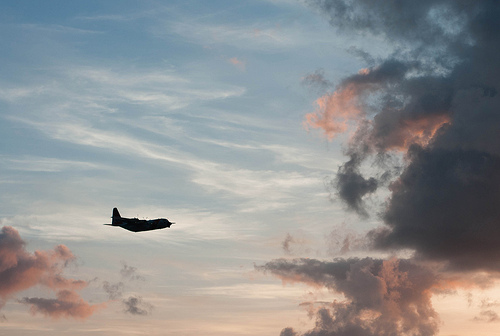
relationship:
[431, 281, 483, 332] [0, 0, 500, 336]
hue under cloud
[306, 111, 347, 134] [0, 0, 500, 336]
sun shining through cloud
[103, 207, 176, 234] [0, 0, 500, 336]
airplane flying above cloud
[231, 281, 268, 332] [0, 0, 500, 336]
sunlight peaking out cloud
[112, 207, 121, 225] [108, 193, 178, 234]
tail of jet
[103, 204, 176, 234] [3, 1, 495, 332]
airplane in sky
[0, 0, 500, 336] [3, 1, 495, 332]
cloud in sky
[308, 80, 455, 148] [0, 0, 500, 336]
sun shines through cloud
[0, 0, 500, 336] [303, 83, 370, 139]
cloud have hue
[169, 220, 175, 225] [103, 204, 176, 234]
wing attached to airplane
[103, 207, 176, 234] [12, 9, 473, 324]
airplane flying at night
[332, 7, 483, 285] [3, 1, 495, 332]
storm cloud hanging in sky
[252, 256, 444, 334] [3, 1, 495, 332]
storm cloud hanging in sky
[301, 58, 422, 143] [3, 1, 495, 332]
storm cloud hanging in sky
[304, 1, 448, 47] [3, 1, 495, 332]
storm cloud hanging in sky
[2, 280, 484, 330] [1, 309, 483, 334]
sunset seen on horizon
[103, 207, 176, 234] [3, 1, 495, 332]
airplane flying in sky